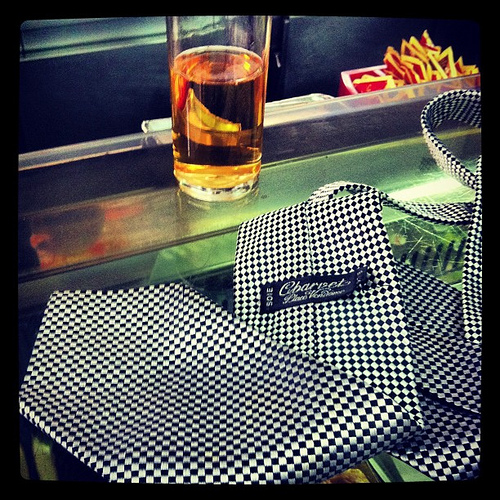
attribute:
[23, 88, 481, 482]
tie — with skinny part , black and white, checkered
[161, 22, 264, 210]
glass —  with wine,  white, reflective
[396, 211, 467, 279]
scratches —  of glass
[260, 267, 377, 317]
tag —  black,  tie's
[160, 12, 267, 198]
glass —  clear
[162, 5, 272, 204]
glass — clear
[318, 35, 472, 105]
box — red and white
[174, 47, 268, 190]
liquid —  gold, brown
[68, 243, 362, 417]
tie — black and white, diamond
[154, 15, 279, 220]
glass — half filled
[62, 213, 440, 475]
tie — checkered, black and white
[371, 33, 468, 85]
packets — yellow and red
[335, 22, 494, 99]
box — of red hot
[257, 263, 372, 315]
tag — black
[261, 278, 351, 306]
white writing —  white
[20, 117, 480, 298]
glass shelf — clear, skinny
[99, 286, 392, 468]
tie —  checkered ,  black and white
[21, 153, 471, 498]
tie —  long, for neck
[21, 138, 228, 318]
glass — reflective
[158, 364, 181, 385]
design —  small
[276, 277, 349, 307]
lettering — white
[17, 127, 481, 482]
glass — green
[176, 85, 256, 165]
shadow —  small 